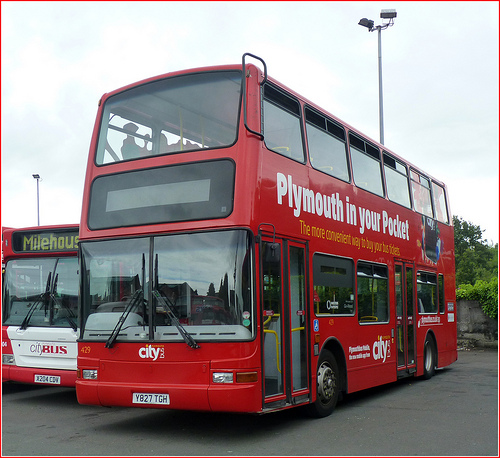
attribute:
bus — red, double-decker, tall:
[74, 54, 455, 415]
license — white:
[132, 394, 172, 404]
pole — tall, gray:
[359, 11, 397, 147]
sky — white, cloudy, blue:
[0, 2, 497, 246]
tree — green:
[449, 216, 498, 318]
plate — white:
[33, 373, 62, 386]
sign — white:
[274, 168, 410, 241]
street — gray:
[4, 344, 498, 457]